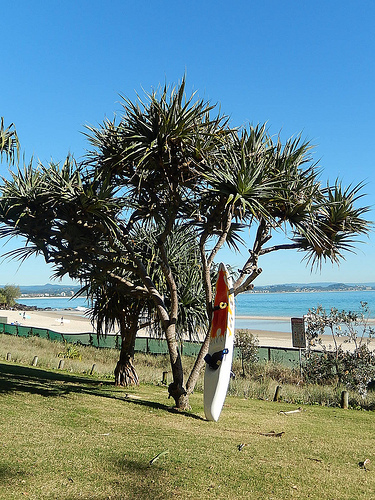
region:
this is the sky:
[157, 15, 304, 64]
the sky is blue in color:
[264, 3, 373, 71]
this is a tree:
[104, 96, 203, 274]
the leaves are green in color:
[158, 126, 192, 161]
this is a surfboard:
[207, 267, 237, 424]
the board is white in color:
[207, 381, 228, 413]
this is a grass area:
[159, 431, 334, 469]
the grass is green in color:
[157, 427, 219, 483]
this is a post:
[289, 315, 302, 340]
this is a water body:
[265, 288, 285, 308]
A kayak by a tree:
[203, 267, 233, 421]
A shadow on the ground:
[1, 363, 110, 398]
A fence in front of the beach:
[5, 325, 368, 371]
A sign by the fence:
[289, 317, 304, 375]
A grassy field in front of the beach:
[3, 336, 374, 498]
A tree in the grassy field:
[8, 121, 353, 407]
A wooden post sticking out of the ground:
[274, 385, 283, 401]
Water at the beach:
[27, 289, 369, 316]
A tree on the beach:
[0, 284, 20, 308]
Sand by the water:
[7, 314, 370, 334]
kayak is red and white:
[208, 263, 242, 422]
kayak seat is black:
[205, 338, 230, 374]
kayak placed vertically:
[196, 284, 235, 438]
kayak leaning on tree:
[195, 280, 231, 422]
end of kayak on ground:
[193, 277, 235, 428]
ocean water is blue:
[279, 292, 349, 320]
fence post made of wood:
[273, 383, 284, 403]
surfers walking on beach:
[18, 310, 77, 329]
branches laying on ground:
[277, 407, 370, 482]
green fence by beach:
[259, 345, 317, 376]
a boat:
[203, 263, 237, 430]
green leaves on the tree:
[15, 178, 124, 238]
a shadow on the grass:
[10, 369, 98, 407]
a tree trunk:
[162, 333, 201, 417]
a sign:
[287, 311, 314, 350]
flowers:
[310, 308, 360, 328]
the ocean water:
[271, 290, 320, 311]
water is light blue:
[259, 295, 298, 311]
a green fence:
[61, 331, 101, 344]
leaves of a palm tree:
[1, 127, 19, 154]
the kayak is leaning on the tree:
[210, 252, 244, 309]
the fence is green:
[275, 356, 298, 365]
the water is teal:
[259, 292, 276, 309]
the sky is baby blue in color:
[268, 21, 313, 72]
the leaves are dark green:
[291, 195, 316, 226]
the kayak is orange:
[213, 286, 224, 305]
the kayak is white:
[205, 370, 218, 395]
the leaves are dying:
[312, 313, 336, 328]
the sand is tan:
[67, 319, 83, 328]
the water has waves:
[252, 295, 284, 310]